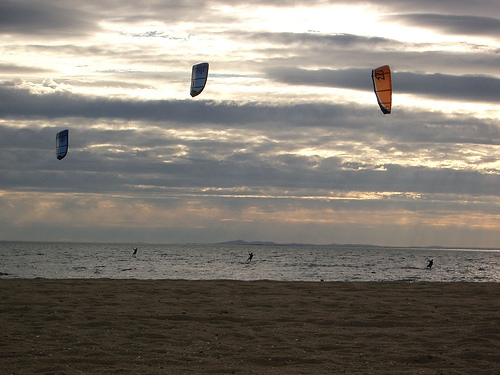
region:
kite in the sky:
[363, 63, 400, 115]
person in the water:
[238, 243, 262, 264]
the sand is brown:
[141, 302, 277, 358]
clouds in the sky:
[245, 123, 345, 179]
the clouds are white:
[192, 122, 288, 184]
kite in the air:
[47, 128, 74, 160]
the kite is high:
[180, 63, 218, 97]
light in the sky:
[86, 80, 136, 99]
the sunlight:
[234, 75, 290, 106]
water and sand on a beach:
[11, 230, 479, 362]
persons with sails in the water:
[39, 58, 486, 280]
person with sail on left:
[28, 115, 168, 268]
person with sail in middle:
[177, 59, 282, 274]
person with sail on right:
[363, 65, 453, 278]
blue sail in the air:
[34, 105, 80, 161]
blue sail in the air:
[176, 60, 221, 100]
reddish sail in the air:
[343, 58, 416, 118]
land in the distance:
[212, 230, 352, 245]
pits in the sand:
[172, 333, 293, 367]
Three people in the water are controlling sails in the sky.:
[53, 62, 436, 272]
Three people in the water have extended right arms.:
[129, 245, 434, 270]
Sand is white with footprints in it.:
[1, 276, 498, 373]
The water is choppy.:
[0, 247, 499, 282]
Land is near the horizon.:
[201, 228, 498, 280]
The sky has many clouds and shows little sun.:
[1, 0, 499, 247]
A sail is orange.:
[372, 62, 393, 116]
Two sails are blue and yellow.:
[55, 61, 209, 159]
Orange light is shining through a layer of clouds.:
[0, 191, 499, 231]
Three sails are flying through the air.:
[53, 61, 393, 160]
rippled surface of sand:
[5, 275, 491, 366]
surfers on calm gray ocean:
[5, 237, 495, 278]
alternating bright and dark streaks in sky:
[0, 2, 495, 242]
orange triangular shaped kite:
[365, 60, 392, 115]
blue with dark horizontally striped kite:
[185, 55, 206, 95]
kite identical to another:
[52, 125, 69, 160]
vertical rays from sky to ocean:
[400, 160, 482, 240]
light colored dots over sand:
[46, 326, 331, 361]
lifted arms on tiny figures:
[125, 240, 435, 275]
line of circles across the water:
[282, 258, 373, 269]